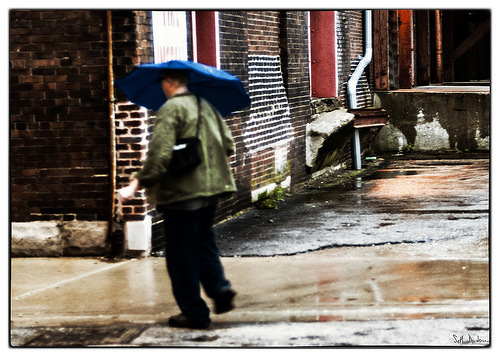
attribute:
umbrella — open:
[107, 46, 262, 103]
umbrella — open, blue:
[104, 29, 247, 100]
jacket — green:
[125, 92, 233, 194]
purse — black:
[120, 139, 239, 202]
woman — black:
[130, 88, 260, 318]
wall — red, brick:
[20, 65, 100, 213]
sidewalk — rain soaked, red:
[286, 257, 367, 301]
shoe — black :
[140, 274, 283, 337]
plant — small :
[242, 118, 386, 244]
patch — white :
[404, 86, 462, 188]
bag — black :
[105, 104, 224, 276]